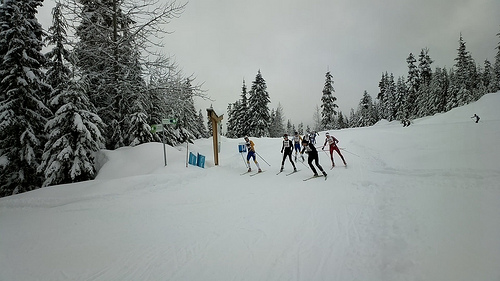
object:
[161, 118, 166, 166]
pole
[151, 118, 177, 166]
sign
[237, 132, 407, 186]
speeds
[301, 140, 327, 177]
skier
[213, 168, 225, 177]
snow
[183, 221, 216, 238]
snow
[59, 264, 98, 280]
snow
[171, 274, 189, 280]
snow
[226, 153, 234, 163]
snow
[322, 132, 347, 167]
skier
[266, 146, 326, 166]
tag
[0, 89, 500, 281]
hillside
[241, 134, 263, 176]
skier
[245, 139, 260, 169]
suit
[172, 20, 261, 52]
sky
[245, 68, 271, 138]
tree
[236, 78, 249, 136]
tree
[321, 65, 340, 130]
tree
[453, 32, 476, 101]
tree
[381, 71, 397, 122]
tree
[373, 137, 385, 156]
ground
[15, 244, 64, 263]
ground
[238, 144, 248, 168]
flag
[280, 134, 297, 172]
skiers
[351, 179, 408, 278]
trail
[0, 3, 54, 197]
trees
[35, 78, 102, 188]
trees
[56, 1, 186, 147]
trees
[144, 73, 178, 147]
trees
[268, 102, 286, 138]
trees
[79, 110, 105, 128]
branches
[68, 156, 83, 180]
branches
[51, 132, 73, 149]
branches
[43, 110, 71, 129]
branches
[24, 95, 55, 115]
branches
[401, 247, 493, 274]
snow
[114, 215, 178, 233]
snow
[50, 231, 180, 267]
snow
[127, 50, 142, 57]
branch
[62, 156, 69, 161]
leaves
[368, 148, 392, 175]
tracks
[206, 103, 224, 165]
marker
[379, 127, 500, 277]
slope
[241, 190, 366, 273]
ground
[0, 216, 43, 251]
snow